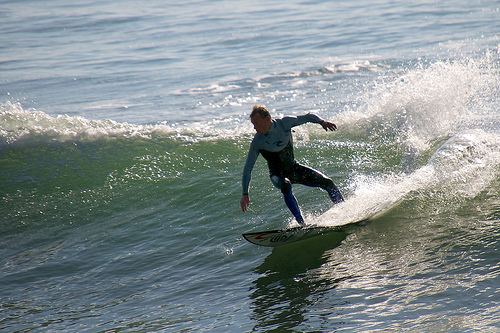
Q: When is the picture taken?
A: Daytime.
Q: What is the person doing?
A: Surfing.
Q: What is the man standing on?
A: A surfboard.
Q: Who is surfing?
A: A man.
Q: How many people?
A: One.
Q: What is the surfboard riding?
A: The wave.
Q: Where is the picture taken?
A: At ocean.